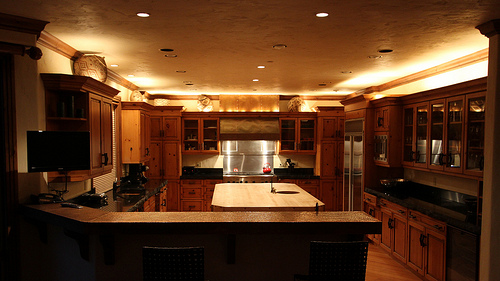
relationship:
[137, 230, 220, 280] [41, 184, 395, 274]
chair in front of counter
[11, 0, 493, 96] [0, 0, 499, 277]
ceiling at top of room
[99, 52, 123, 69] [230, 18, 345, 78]
light on ceiling